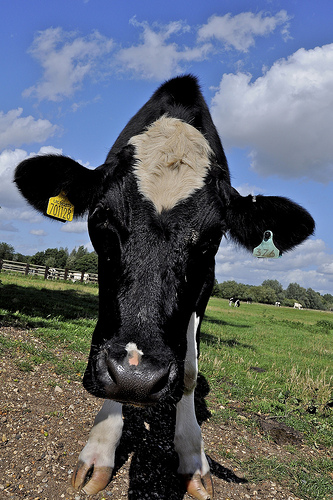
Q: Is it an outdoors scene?
A: Yes, it is outdoors.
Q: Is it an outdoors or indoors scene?
A: It is outdoors.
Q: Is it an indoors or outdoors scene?
A: It is outdoors.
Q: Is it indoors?
A: No, it is outdoors.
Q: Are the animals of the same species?
A: Yes, all the animals are cows.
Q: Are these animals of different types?
A: No, all the animals are cows.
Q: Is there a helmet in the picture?
A: No, there are no helmets.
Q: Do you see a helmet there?
A: No, there are no helmets.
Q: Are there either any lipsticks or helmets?
A: No, there are no helmets or lipsticks.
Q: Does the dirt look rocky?
A: Yes, the dirt is rocky.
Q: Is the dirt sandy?
A: No, the dirt is rocky.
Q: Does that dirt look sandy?
A: No, the dirt is rocky.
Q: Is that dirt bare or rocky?
A: The dirt is rocky.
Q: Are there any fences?
A: Yes, there is a fence.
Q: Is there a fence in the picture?
A: Yes, there is a fence.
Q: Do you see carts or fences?
A: Yes, there is a fence.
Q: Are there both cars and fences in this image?
A: No, there is a fence but no cars.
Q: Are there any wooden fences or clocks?
A: Yes, there is a wood fence.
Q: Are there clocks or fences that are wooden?
A: Yes, the fence is wooden.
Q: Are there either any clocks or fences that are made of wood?
A: Yes, the fence is made of wood.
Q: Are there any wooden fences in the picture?
A: Yes, there is a wood fence.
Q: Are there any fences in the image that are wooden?
A: Yes, there is a fence that is wooden.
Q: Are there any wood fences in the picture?
A: Yes, there is a fence that is made of wood.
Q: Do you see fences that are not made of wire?
A: Yes, there is a fence that is made of wood.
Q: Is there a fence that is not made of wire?
A: Yes, there is a fence that is made of wood.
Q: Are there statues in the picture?
A: No, there are no statues.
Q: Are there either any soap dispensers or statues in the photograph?
A: No, there are no statues or soap dispensers.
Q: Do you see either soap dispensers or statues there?
A: No, there are no statues or soap dispensers.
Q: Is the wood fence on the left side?
A: Yes, the fence is on the left of the image.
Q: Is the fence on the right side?
A: No, the fence is on the left of the image.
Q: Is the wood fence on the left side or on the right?
A: The fence is on the left of the image.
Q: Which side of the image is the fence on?
A: The fence is on the left of the image.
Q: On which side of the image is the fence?
A: The fence is on the left of the image.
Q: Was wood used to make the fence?
A: Yes, the fence is made of wood.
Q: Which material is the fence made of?
A: The fence is made of wood.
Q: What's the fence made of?
A: The fence is made of wood.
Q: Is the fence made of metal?
A: No, the fence is made of wood.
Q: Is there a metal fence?
A: No, there is a fence but it is made of wood.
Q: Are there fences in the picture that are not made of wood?
A: No, there is a fence but it is made of wood.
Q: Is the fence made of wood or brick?
A: The fence is made of wood.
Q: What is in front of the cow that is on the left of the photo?
A: The fence is in front of the cow.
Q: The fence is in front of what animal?
A: The fence is in front of the cow.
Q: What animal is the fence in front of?
A: The fence is in front of the cow.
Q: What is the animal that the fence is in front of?
A: The animal is a cow.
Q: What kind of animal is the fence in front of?
A: The fence is in front of the cow.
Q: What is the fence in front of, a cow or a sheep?
A: The fence is in front of a cow.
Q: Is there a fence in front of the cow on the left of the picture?
A: Yes, there is a fence in front of the cow.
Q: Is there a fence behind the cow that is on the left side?
A: No, the fence is in front of the cow.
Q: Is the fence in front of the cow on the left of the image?
A: Yes, the fence is in front of the cow.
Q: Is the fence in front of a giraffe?
A: No, the fence is in front of the cow.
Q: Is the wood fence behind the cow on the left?
A: No, the fence is in front of the cow.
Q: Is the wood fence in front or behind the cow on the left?
A: The fence is in front of the cow.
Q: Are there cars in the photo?
A: No, there are no cars.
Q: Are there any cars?
A: No, there are no cars.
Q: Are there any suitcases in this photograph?
A: No, there are no suitcases.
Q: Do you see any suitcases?
A: No, there are no suitcases.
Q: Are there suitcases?
A: No, there are no suitcases.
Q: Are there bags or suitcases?
A: No, there are no suitcases or bags.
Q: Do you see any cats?
A: No, there are no cats.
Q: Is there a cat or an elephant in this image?
A: No, there are no cats or elephants.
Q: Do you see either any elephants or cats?
A: No, there are no cats or elephants.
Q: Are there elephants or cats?
A: No, there are no cats or elephants.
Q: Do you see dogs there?
A: No, there are no dogs.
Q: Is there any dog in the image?
A: No, there are no dogs.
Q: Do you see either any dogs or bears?
A: No, there are no dogs or bears.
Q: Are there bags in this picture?
A: No, there are no bags.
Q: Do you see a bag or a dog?
A: No, there are no bags or dogs.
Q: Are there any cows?
A: Yes, there is a cow.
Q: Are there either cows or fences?
A: Yes, there is a cow.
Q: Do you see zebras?
A: No, there are no zebras.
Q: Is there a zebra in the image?
A: No, there are no zebras.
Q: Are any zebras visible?
A: No, there are no zebras.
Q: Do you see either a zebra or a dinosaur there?
A: No, there are no zebras or dinosaurs.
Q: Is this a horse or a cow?
A: This is a cow.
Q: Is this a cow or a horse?
A: This is a cow.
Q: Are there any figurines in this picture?
A: No, there are no figurines.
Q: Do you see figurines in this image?
A: No, there are no figurines.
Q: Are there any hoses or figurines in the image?
A: No, there are no figurines or hoses.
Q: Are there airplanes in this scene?
A: No, there are no airplanes.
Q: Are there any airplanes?
A: No, there are no airplanes.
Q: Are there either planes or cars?
A: No, there are no planes or cars.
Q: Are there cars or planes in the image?
A: No, there are no planes or cars.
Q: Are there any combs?
A: No, there are no combs.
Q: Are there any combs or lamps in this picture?
A: No, there are no combs or lamps.